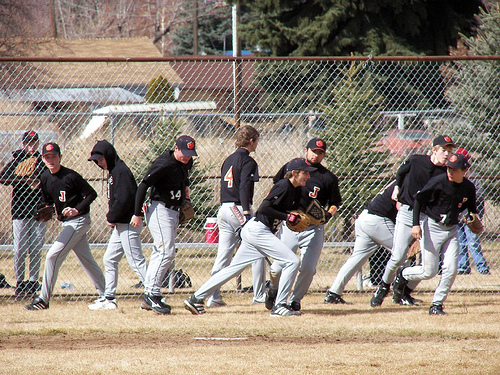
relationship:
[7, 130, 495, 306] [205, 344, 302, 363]
baseball players on field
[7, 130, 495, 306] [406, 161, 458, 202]
baseball players in black shirts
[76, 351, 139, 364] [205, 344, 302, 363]
grass on field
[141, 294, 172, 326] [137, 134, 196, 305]
black sneaker on baseball player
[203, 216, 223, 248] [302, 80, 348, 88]
red cooler behind fence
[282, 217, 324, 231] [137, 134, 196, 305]
glove of baseball player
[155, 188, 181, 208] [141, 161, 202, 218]
number on shirt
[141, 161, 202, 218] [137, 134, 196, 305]
shirt of baseball player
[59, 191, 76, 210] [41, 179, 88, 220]
letter on shirt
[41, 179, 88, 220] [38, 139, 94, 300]
shirt of guy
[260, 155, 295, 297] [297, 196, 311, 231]
player with mitt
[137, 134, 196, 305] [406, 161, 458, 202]
baseball player in black shirts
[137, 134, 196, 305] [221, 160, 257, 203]
baseball player in black shirt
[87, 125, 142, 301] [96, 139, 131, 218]
dude in hoodie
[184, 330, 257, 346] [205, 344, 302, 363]
white plate on field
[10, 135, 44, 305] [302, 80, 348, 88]
buddy behind fence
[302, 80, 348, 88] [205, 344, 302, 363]
fence separates field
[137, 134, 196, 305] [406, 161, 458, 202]
baseball player wears black shirts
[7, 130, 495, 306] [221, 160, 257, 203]
baseball players in black shirt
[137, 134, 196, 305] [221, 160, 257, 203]
baseball player wears black shirt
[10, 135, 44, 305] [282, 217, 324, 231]
buddy holding glove